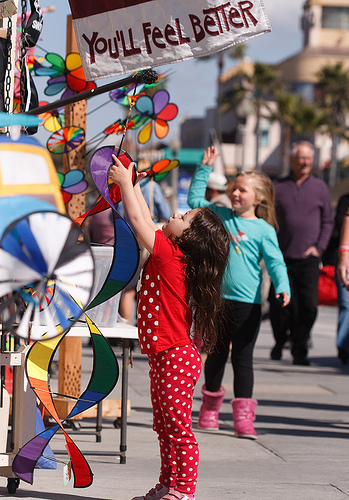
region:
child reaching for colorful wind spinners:
[61, 110, 233, 494]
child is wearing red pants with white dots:
[149, 339, 209, 492]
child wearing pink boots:
[192, 379, 278, 447]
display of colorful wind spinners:
[29, 99, 147, 487]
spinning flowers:
[116, 83, 179, 148]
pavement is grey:
[219, 438, 314, 480]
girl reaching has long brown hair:
[166, 199, 225, 355]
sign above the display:
[51, 0, 281, 57]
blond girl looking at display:
[215, 161, 282, 227]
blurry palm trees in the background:
[196, 52, 341, 152]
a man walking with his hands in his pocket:
[262, 124, 336, 372]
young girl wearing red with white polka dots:
[122, 196, 220, 498]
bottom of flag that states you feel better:
[62, 8, 285, 86]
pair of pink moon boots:
[194, 370, 267, 441]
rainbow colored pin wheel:
[104, 85, 178, 161]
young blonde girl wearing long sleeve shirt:
[181, 129, 297, 452]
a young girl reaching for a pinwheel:
[60, 90, 245, 498]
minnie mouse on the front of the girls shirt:
[127, 244, 173, 343]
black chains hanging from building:
[3, 6, 49, 119]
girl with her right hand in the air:
[186, 135, 302, 321]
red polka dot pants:
[134, 345, 210, 498]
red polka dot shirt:
[127, 224, 201, 353]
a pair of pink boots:
[186, 377, 266, 447]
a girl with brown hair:
[93, 145, 239, 495]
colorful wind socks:
[3, 127, 149, 490]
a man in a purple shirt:
[266, 139, 336, 372]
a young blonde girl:
[186, 143, 296, 445]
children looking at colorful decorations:
[4, 129, 303, 493]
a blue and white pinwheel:
[1, 202, 98, 352]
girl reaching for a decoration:
[12, 139, 233, 498]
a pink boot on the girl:
[227, 390, 255, 442]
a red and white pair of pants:
[140, 338, 198, 489]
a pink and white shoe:
[159, 484, 190, 494]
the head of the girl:
[158, 196, 230, 270]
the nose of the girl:
[171, 209, 183, 221]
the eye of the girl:
[178, 212, 186, 222]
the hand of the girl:
[102, 149, 138, 186]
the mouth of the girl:
[163, 214, 171, 226]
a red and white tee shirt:
[133, 226, 193, 357]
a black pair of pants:
[199, 296, 264, 399]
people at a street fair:
[3, 2, 340, 497]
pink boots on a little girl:
[196, 382, 267, 440]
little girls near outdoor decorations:
[96, 141, 293, 496]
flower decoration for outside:
[124, 87, 185, 143]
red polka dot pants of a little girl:
[134, 342, 220, 496]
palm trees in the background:
[220, 54, 348, 143]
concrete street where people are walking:
[206, 442, 344, 490]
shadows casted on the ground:
[265, 394, 346, 441]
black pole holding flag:
[23, 64, 173, 122]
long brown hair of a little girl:
[179, 203, 237, 363]